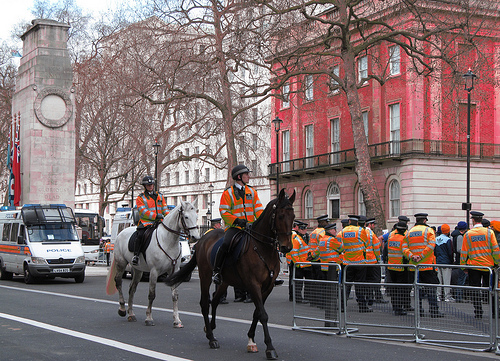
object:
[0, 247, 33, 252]
stripe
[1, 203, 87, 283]
police van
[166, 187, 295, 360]
horse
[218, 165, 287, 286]
policeman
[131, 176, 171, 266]
policeman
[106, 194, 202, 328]
horse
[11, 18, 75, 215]
clocktower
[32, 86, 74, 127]
place-for-clock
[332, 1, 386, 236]
tree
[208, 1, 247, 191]
tree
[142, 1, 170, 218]
tree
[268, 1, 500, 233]
building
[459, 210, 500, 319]
cops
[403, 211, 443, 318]
cops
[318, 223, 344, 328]
cops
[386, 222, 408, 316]
cops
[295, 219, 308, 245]
cops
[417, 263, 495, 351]
barricade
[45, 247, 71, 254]
police sign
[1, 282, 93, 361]
street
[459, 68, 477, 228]
streetlight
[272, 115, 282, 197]
streetlight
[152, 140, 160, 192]
streetlight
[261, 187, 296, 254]
head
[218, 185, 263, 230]
vest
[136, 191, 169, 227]
vest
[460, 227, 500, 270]
vest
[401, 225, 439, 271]
vest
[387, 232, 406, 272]
vest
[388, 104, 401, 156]
window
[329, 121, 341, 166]
window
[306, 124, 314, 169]
window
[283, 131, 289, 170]
window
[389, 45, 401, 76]
window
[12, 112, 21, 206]
flag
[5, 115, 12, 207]
flag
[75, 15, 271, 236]
building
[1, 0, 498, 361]
city